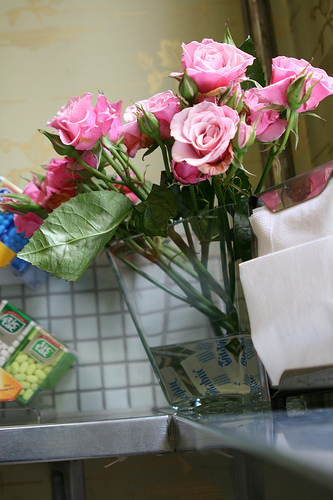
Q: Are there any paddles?
A: No, there are no paddles.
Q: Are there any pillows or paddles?
A: No, there are no paddles or pillows.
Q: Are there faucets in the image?
A: No, there are no faucets.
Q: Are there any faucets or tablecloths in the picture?
A: No, there are no faucets or tablecloths.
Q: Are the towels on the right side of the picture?
A: Yes, the towels are on the right of the image.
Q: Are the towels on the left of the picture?
A: No, the towels are on the right of the image.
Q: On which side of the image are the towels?
A: The towels are on the right of the image.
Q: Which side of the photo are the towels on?
A: The towels are on the right of the image.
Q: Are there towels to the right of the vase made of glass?
A: Yes, there are towels to the right of the vase.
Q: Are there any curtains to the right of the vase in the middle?
A: No, there are towels to the right of the vase.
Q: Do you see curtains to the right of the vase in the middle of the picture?
A: No, there are towels to the right of the vase.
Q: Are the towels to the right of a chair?
A: No, the towels are to the right of a vase.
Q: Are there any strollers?
A: No, there are no strollers.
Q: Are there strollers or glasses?
A: No, there are no strollers or glasses.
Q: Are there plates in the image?
A: No, there are no plates.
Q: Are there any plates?
A: No, there are no plates.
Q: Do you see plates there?
A: No, there are no plates.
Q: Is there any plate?
A: No, there are no plates.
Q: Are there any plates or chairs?
A: No, there are no plates or chairs.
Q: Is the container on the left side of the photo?
A: Yes, the container is on the left of the image.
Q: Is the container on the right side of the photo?
A: No, the container is on the left of the image.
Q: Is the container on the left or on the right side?
A: The container is on the left of the image.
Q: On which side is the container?
A: The container is on the left of the image.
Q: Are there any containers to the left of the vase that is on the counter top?
A: Yes, there is a container to the left of the vase.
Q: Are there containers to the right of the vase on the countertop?
A: No, the container is to the left of the vase.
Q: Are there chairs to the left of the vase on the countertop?
A: No, there is a container to the left of the vase.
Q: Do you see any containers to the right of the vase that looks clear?
A: No, the container is to the left of the vase.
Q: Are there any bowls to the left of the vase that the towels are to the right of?
A: No, there is a container to the left of the vase.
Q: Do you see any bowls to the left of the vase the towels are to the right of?
A: No, there is a container to the left of the vase.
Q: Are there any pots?
A: No, there are no pots.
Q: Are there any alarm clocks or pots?
A: No, there are no pots or alarm clocks.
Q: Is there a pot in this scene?
A: No, there are no pots.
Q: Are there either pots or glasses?
A: No, there are no pots or glasses.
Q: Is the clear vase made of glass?
A: Yes, the vase is made of glass.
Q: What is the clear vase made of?
A: The vase is made of glass.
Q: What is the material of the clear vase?
A: The vase is made of glass.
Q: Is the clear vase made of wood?
A: No, the vase is made of glass.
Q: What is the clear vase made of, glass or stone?
A: The vase is made of glass.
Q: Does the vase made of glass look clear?
A: Yes, the vase is clear.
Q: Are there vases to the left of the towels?
A: Yes, there is a vase to the left of the towels.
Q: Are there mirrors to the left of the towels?
A: No, there is a vase to the left of the towels.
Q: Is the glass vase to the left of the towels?
A: Yes, the vase is to the left of the towels.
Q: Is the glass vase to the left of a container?
A: No, the vase is to the right of a container.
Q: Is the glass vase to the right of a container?
A: Yes, the vase is to the right of a container.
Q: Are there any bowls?
A: No, there are no bowls.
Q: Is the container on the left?
A: Yes, the container is on the left of the image.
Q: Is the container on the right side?
A: No, the container is on the left of the image.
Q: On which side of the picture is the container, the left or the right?
A: The container is on the left of the image.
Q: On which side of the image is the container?
A: The container is on the left of the image.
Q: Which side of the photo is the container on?
A: The container is on the left of the image.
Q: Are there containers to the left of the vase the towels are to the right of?
A: Yes, there is a container to the left of the vase.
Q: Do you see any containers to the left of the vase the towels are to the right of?
A: Yes, there is a container to the left of the vase.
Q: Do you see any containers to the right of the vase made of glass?
A: No, the container is to the left of the vase.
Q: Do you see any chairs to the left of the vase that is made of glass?
A: No, there is a container to the left of the vase.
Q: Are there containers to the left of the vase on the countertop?
A: Yes, there is a container to the left of the vase.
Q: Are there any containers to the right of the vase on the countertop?
A: No, the container is to the left of the vase.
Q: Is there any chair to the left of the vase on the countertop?
A: No, there is a container to the left of the vase.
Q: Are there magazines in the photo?
A: No, there are no magazines.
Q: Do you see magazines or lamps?
A: No, there are no magazines or lamps.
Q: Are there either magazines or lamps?
A: No, there are no magazines or lamps.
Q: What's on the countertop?
A: The vase is on the countertop.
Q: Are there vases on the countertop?
A: Yes, there is a vase on the countertop.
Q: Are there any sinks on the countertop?
A: No, there is a vase on the countertop.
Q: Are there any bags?
A: No, there are no bags.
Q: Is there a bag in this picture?
A: No, there are no bags.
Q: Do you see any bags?
A: No, there are no bags.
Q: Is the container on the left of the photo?
A: Yes, the container is on the left of the image.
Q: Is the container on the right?
A: No, the container is on the left of the image.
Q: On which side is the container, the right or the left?
A: The container is on the left of the image.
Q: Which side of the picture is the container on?
A: The container is on the left of the image.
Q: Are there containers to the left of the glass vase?
A: Yes, there is a container to the left of the vase.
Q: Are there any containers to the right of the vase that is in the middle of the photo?
A: No, the container is to the left of the vase.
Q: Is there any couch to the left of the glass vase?
A: No, there is a container to the left of the vase.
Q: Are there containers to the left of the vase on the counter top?
A: Yes, there is a container to the left of the vase.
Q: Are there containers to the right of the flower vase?
A: No, the container is to the left of the vase.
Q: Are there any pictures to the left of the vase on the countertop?
A: No, there is a container to the left of the vase.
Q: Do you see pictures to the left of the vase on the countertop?
A: No, there is a container to the left of the vase.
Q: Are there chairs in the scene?
A: No, there are no chairs.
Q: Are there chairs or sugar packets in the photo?
A: No, there are no chairs or sugar packets.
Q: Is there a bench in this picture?
A: No, there are no benches.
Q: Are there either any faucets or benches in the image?
A: No, there are no benches or faucets.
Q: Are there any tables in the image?
A: Yes, there is a table.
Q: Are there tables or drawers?
A: Yes, there is a table.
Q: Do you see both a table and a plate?
A: No, there is a table but no plates.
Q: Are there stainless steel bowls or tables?
A: Yes, there is a stainless steel table.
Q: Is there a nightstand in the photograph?
A: No, there are no nightstands.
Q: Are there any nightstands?
A: No, there are no nightstands.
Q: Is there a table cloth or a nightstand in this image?
A: No, there are no nightstands or tablecloths.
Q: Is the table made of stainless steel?
A: Yes, the table is made of stainless steel.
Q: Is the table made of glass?
A: No, the table is made of stainless steel.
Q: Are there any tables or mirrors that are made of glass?
A: No, there is a table but it is made of stainless steel.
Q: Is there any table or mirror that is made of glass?
A: No, there is a table but it is made of stainless steel.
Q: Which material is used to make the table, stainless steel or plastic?
A: The table is made of stainless steel.